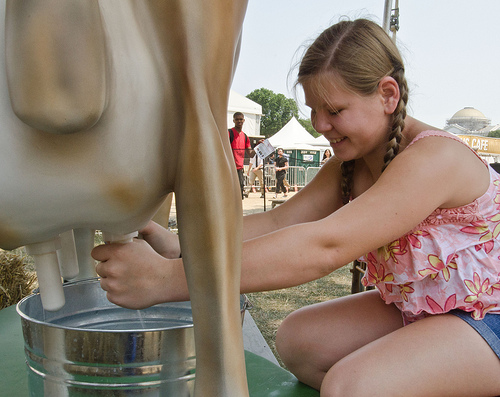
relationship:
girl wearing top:
[252, 14, 499, 395] [397, 230, 500, 304]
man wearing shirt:
[228, 111, 255, 170] [232, 132, 244, 164]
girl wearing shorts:
[252, 14, 499, 395] [466, 316, 500, 351]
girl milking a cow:
[252, 14, 499, 395] [3, 1, 249, 396]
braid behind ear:
[388, 85, 409, 159] [379, 77, 400, 115]